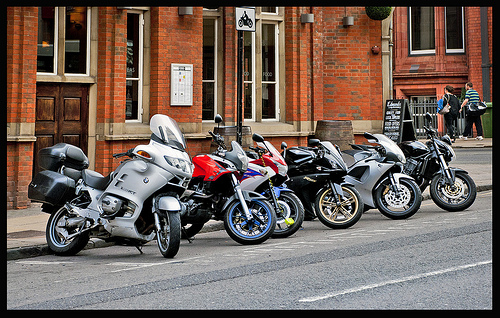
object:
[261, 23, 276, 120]
window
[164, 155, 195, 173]
light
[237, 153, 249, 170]
light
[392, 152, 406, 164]
light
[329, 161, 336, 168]
light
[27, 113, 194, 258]
motorcycle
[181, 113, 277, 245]
motorcycle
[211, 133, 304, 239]
motorcycle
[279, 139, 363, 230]
motorcycle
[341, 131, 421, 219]
motorcycle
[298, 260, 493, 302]
line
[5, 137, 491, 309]
street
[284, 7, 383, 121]
brick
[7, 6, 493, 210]
building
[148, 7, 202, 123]
brick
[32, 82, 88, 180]
door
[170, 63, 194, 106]
sign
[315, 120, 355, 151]
barrel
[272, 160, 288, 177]
light